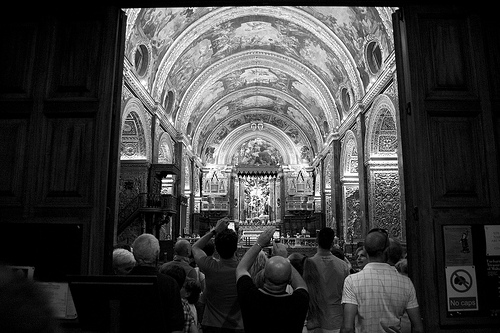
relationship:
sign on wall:
[443, 261, 483, 312] [392, 6, 484, 330]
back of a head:
[249, 257, 308, 324] [260, 251, 294, 287]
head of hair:
[129, 228, 167, 266] [130, 231, 165, 262]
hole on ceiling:
[127, 41, 156, 77] [117, 11, 397, 131]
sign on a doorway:
[443, 261, 483, 312] [60, 27, 475, 303]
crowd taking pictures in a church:
[120, 222, 420, 322] [81, 18, 442, 302]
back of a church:
[213, 140, 306, 224] [78, 14, 435, 284]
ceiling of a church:
[115, 13, 400, 164] [81, 18, 442, 302]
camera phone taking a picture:
[272, 227, 281, 243] [274, 232, 277, 240]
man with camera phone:
[231, 223, 312, 323] [272, 227, 281, 241]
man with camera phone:
[189, 214, 245, 318] [228, 217, 239, 231]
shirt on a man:
[342, 260, 416, 324] [330, 223, 420, 332]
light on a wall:
[160, 165, 177, 209] [116, 134, 200, 234]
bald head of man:
[265, 256, 292, 288] [231, 223, 312, 323]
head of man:
[129, 232, 162, 265] [110, 222, 185, 323]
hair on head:
[129, 232, 161, 259] [129, 232, 162, 265]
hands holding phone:
[257, 219, 290, 253] [269, 226, 281, 238]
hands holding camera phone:
[219, 216, 243, 229] [228, 219, 238, 232]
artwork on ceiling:
[118, 6, 399, 172] [115, 13, 400, 164]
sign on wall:
[443, 261, 483, 312] [80, 12, 476, 320]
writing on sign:
[448, 293, 478, 313] [446, 261, 478, 316]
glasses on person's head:
[369, 225, 389, 240] [363, 224, 392, 257]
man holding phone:
[189, 214, 260, 329] [227, 218, 238, 234]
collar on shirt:
[363, 259, 393, 273] [342, 260, 425, 330]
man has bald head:
[231, 223, 312, 333] [258, 252, 297, 289]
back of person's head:
[220, 236, 233, 250] [206, 216, 242, 260]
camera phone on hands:
[272, 227, 281, 243] [259, 221, 273, 241]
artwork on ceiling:
[137, 8, 395, 160] [132, 10, 397, 168]